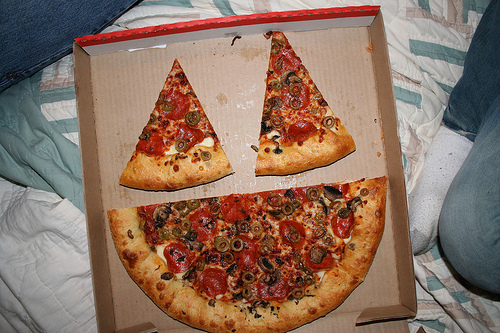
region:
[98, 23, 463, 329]
Pizze in box arranged like face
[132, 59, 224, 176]
slice of pizza in box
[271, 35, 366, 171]
slice of pizza in box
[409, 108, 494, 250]
white sock by pizza box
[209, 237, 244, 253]
olives on top of pizza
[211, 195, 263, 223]
pepperoni on pizza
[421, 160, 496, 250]
denim jean on knee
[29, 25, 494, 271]
white comforter on bed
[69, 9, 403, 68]
red edge of cardboard box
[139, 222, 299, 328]
golden crust of pizza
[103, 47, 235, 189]
a full slice of pizza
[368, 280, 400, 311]
the box is brown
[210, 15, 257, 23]
the edge of the box is red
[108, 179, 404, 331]
half of a pizza in a cardboard box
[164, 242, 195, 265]
the peperroni is red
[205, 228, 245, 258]
the olives are round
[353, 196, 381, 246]
the crust is thick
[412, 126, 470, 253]
the foot is on the bed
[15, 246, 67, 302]
the blanket is white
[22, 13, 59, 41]
the jeans are blue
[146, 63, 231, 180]
one slice of pizza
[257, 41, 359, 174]
one slice of pizza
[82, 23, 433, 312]
pizza in a box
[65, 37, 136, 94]
corner of cardboard box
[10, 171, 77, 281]
comforter on the bed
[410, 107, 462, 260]
white socks in photo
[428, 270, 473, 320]
corner of bed comforter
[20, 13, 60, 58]
blue jeans on person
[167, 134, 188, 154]
olive on the pizza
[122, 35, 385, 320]
pizza in a box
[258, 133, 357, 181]
crust of the pizza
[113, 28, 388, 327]
pizza made to look like face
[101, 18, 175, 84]
red and white box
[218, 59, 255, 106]
brown box under pizza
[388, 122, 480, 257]
sock next to the box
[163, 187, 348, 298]
toppings on the pizza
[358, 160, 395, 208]
corner of the pizza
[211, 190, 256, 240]
red topping on the pizza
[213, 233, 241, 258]
circular toppings on pizza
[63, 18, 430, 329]
Pizza in the box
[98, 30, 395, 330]
Three slices of pizza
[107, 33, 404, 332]
One big and two small pizza slices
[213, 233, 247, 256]
Green olive slices on pizza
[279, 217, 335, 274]
Tomato topping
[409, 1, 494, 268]
A person sitting on the bed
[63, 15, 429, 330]
Pizza box on the bed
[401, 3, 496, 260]
A person wearing a pair of jeans and white socks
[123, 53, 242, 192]
Yummy pizza slice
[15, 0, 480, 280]
Quilt on the bed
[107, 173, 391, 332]
the bottom half of a pizza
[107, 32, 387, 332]
pizza that looks like a face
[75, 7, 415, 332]
a box containing pizza